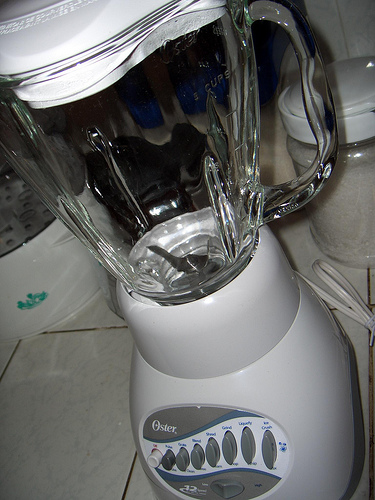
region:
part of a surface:
[76, 460, 85, 472]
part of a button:
[262, 440, 286, 457]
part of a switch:
[212, 479, 244, 496]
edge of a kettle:
[313, 418, 318, 444]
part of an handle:
[312, 174, 325, 190]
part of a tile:
[73, 426, 97, 454]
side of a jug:
[307, 432, 320, 464]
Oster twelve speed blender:
[63, 4, 366, 499]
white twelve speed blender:
[70, 16, 364, 498]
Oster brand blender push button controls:
[134, 398, 309, 498]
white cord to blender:
[287, 250, 373, 340]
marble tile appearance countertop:
[2, 338, 130, 491]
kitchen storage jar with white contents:
[273, 61, 373, 272]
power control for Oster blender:
[189, 475, 256, 497]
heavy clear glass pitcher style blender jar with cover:
[2, 2, 328, 304]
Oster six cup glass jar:
[1, 21, 344, 299]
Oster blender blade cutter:
[132, 240, 232, 291]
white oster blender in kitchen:
[2, 1, 364, 496]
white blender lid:
[1, 0, 222, 112]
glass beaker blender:
[2, 2, 336, 308]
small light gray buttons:
[172, 425, 277, 473]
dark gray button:
[159, 448, 171, 464]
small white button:
[144, 451, 162, 467]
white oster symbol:
[147, 417, 177, 436]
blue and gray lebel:
[139, 403, 290, 496]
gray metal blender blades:
[140, 237, 215, 284]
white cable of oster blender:
[297, 256, 372, 340]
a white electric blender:
[2, 0, 356, 497]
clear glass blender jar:
[3, 2, 336, 302]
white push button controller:
[145, 445, 157, 468]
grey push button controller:
[158, 446, 173, 469]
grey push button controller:
[174, 443, 185, 469]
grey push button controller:
[187, 442, 202, 468]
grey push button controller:
[203, 432, 218, 465]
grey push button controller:
[219, 428, 234, 463]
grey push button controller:
[238, 425, 251, 462]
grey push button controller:
[259, 427, 276, 470]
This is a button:
[258, 423, 281, 472]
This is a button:
[236, 420, 254, 461]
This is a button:
[218, 424, 238, 469]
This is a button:
[202, 435, 218, 468]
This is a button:
[185, 440, 203, 470]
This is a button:
[172, 442, 188, 474]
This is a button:
[159, 446, 174, 470]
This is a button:
[143, 444, 160, 467]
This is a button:
[195, 474, 248, 497]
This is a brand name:
[149, 409, 183, 436]